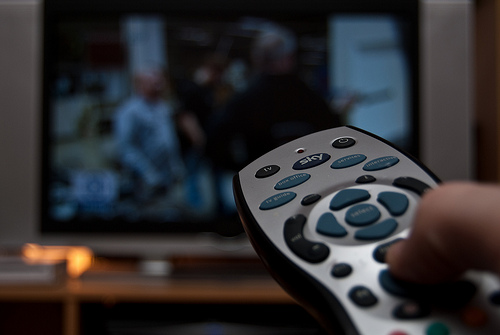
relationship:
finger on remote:
[390, 178, 498, 287] [203, 96, 483, 333]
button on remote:
[257, 197, 291, 217] [223, 109, 500, 335]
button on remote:
[313, 180, 409, 247] [223, 109, 500, 335]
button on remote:
[279, 211, 328, 269] [223, 109, 500, 335]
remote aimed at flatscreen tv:
[223, 109, 500, 335] [5, 1, 476, 258]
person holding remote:
[389, 178, 498, 330] [223, 109, 500, 335]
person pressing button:
[379, 178, 498, 331] [377, 262, 412, 301]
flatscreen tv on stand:
[5, 1, 476, 258] [1, 245, 405, 333]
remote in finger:
[223, 109, 500, 335] [390, 178, 498, 287]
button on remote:
[293, 148, 329, 170] [215, 140, 440, 332]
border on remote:
[232, 184, 270, 274] [223, 109, 500, 335]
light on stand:
[17, 239, 95, 293] [1, 245, 405, 333]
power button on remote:
[331, 131, 358, 151] [221, 142, 459, 331]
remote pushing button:
[223, 109, 421, 325] [377, 239, 409, 266]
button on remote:
[281, 211, 328, 264] [223, 109, 500, 335]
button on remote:
[345, 202, 381, 227] [223, 109, 500, 335]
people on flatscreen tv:
[115, 23, 332, 122] [5, 1, 476, 258]